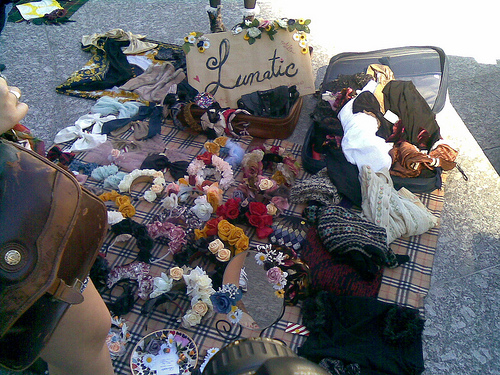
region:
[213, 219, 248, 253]
a set of orange roses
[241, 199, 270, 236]
a set of red roses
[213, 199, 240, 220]
a set of red roses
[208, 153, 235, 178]
a set of pink roses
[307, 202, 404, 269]
a multi colored scarf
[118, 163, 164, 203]
a flowered head band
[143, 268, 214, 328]
a flowered head band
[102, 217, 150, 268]
a flowered head band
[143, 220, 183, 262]
a flowered head band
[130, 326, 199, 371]
a colorful decorative plate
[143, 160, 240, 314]
Flowers on a blanket.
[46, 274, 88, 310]
Srap of a bag.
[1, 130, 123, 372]
A brown fading leather purse.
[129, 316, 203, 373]
A plate with flower design.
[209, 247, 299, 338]
A round mirror.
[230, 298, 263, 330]
Painted toe nails in reflection.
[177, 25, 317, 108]
A cardboard sign.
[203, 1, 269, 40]
A pair of boots.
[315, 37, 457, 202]
Cloths in a suitcase.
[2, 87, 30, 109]
A ring on her finger.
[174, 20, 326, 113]
A sign with writing on it.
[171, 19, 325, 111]
Writing on sign in cursive.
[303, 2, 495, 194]
Suitcase is lying on the ground.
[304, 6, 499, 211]
Suitcase is near the curb.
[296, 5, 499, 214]
Clothes in a suitcase.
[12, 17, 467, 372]
Clothes scattered on blanket.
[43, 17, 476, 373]
Flowers of various colors.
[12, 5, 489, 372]
Flowers on a blanket.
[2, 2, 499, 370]
The sidewalk is paved.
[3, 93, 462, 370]
The blanket is checkered.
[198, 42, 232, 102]
this is an l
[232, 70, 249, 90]
this is the letter U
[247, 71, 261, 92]
this is an N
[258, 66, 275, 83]
this is an A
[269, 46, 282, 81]
this is a t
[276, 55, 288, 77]
this is an I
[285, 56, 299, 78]
this is a C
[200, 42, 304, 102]
this is the word Lunatic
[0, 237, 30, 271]
this is a button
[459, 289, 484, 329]
this is the road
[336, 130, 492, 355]
the ground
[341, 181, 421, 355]
the ground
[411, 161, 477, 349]
the ground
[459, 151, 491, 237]
the ground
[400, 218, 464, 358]
the ground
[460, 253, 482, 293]
the ground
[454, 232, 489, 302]
the ground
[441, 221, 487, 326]
the ground